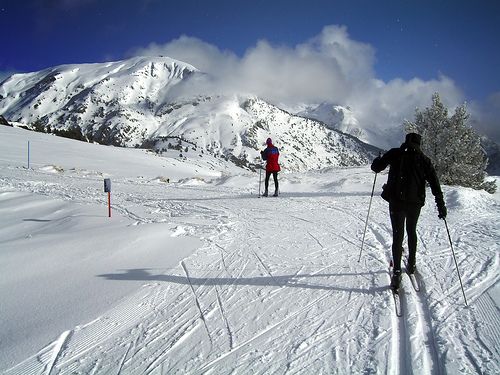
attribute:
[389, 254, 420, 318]
snow skis — white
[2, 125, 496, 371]
snow — white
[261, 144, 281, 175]
coat — blue, red, black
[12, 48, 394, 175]
mountain — snow covered, large, snowy, white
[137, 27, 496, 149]
clouds — white, emerging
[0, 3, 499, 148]
sky — blue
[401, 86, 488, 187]
tree — snow covered, ice covered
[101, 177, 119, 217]
post — red, white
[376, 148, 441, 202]
jacket — black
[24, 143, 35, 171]
pole — blue